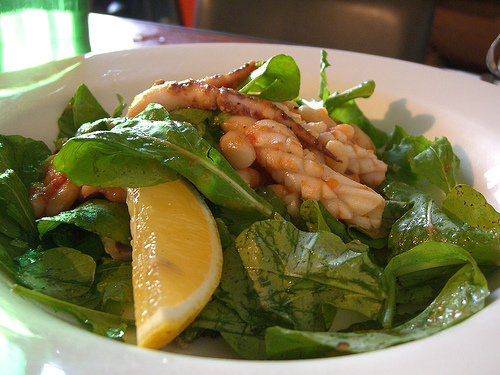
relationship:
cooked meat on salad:
[212, 144, 385, 211] [242, 212, 460, 362]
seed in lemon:
[155, 257, 190, 281] [104, 186, 226, 347]